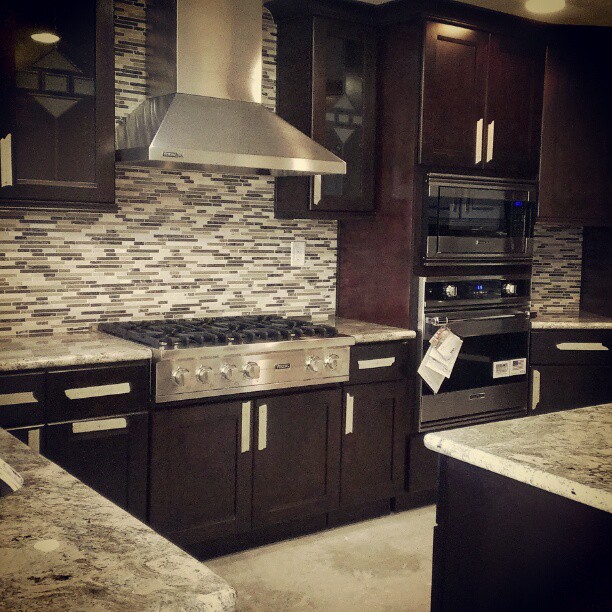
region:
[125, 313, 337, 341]
the range on the stove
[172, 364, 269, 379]
knobs on the stove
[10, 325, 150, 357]
a counter on the stove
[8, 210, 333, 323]
back splash behind the stove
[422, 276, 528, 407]
an oven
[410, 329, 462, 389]
a tag on the oven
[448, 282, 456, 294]
a knob on the oven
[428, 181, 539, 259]
a silver microwave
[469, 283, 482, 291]
the clock on the oven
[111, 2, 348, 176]
gray metal range hood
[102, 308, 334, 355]
black stove in kitchen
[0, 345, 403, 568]
brown wooden cabinets under black stove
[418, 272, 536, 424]
built-in gray oven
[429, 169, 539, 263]
built-in gray microwave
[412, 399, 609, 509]
granite countertops in the corner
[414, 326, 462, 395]
white discloths hanging in the oven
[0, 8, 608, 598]
big clean kitchen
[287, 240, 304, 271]
white plug-in in the wall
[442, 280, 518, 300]
gray oven knobs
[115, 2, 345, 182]
A silver hood in a kitchen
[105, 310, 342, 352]
Burners on a stove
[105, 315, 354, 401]
A stove in a kitchen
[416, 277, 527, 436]
An oven in a kitchen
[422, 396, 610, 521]
A countertop in a kitchen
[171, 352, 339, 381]
Knobs on a stove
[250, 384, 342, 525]
Cabinet door in a kitchen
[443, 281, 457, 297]
Knob on an oven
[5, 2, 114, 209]
a door for a cabinet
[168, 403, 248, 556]
a door for a cabinet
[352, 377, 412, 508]
a door for a cabinet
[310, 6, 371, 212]
a door for a cabinet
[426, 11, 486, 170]
a door for a cabinet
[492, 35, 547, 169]
a door for a cabinet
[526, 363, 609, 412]
a door for a cabinet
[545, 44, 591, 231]
a door for a cabinet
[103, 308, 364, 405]
a gas cooktop stove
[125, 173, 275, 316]
skinny tiles for a backsplash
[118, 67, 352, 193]
vent hood over a cooktop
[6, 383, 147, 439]
tape on door and drawers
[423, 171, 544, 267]
built-in microwave oven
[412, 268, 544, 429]
a built-in oven in a kitchen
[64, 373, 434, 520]
cupboards in a kitchen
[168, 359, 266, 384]
knobs on a cooktop stove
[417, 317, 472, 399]
papers hanging on an oven door